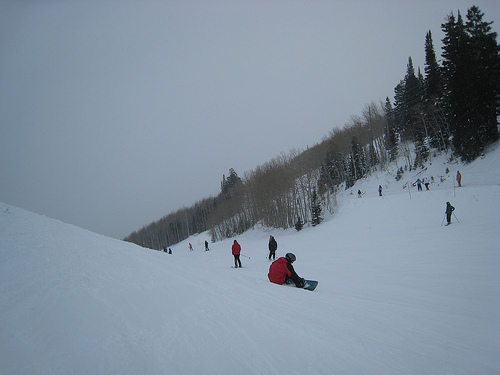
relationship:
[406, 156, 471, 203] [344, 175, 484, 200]
three people walking path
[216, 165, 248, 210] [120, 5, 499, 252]
tree sticking up through forest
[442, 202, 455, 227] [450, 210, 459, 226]
person holding poles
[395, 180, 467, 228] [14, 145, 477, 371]
poles stuck in ground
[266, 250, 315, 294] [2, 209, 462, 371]
man sitting down in snow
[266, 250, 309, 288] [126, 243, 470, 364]
man sitting down on snow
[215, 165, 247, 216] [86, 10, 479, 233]
tree in middle of forest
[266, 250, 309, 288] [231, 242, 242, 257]
man dressed in a red jacket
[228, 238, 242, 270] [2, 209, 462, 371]
person standing in snow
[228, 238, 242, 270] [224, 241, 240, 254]
person in jacket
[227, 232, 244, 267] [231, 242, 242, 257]
person in in a red jacket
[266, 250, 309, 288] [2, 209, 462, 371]
man sitting on snow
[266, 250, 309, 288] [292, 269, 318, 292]
man on snowboad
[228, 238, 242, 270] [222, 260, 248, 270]
person on skiis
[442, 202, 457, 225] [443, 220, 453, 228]
person on some skis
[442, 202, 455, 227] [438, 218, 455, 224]
person on skiis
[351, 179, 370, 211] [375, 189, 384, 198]
person on skiis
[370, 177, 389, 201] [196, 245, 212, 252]
person on skiis